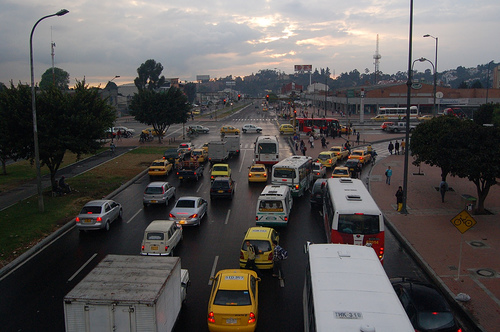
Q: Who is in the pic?
A: No one.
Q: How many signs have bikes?
A: 1.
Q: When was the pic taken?
A: In the evening.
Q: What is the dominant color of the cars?
A: Yellow.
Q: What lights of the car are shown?
A: Brakes.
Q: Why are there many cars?
A: Traffic.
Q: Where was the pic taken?
A: On the road.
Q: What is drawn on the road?
A: Lines.